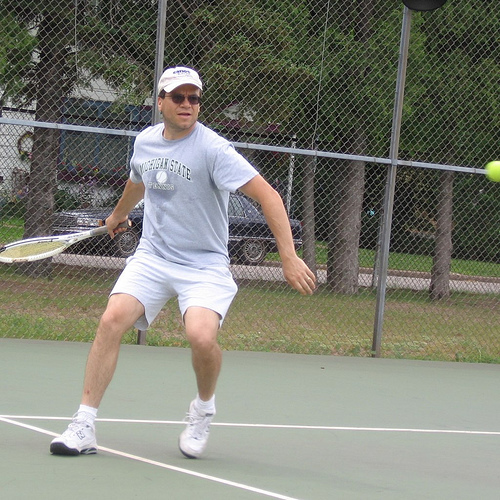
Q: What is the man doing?
A: Playing tennis.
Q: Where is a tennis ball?
A: In the air.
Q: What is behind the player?
A: A fence.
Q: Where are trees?
A: Behind the fence.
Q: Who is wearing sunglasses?
A: Tennis player.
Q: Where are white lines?
A: On the court.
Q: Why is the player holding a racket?
A: To hit the ball.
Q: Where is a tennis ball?
A: In the air.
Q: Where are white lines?
A: On the court.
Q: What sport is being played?
A: Tennis.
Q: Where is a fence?
A: Behind the player.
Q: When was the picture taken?
A: During the daytime.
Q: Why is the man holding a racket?
A: To hit the ball.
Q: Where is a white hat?
A: On man's head.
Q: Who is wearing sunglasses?
A: Tennis player.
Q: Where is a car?
A: On the road.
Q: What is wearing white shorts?
A: The man.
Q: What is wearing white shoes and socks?
A: The man.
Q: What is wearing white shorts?
A: The man.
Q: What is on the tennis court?
A: The metal fence.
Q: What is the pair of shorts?
A: White.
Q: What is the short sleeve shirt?
A: Gray.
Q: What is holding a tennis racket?
A: The man.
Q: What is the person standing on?
A: Tennis court.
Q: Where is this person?
A: On a tennis court.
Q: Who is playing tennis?
A: A man with a white cap.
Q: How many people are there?
A: One.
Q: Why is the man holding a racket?
A: He will hit the ball.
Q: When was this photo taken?
A: During the daytime.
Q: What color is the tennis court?
A: Green.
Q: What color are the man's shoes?
A: White.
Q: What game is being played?
A: Tennis.